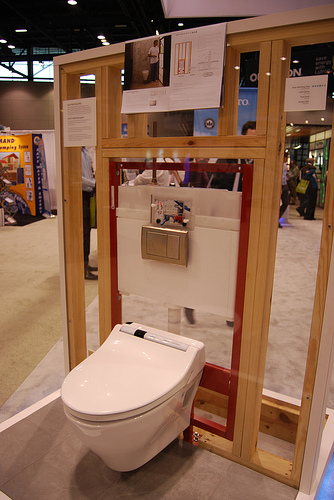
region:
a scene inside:
[4, 3, 333, 494]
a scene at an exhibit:
[1, 2, 325, 497]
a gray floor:
[2, 203, 333, 431]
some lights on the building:
[55, 0, 132, 51]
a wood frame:
[36, 0, 330, 498]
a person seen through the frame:
[77, 117, 110, 296]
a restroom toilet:
[58, 314, 214, 498]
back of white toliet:
[120, 319, 201, 363]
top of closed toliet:
[52, 320, 179, 436]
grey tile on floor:
[182, 472, 225, 492]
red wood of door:
[215, 369, 233, 386]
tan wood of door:
[244, 369, 255, 401]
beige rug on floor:
[19, 330, 51, 373]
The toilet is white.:
[53, 319, 211, 475]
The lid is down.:
[54, 312, 202, 421]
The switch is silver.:
[127, 223, 196, 268]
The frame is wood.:
[51, 62, 332, 409]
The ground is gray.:
[0, 398, 295, 498]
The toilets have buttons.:
[119, 319, 189, 358]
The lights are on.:
[93, 31, 112, 52]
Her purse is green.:
[295, 176, 309, 192]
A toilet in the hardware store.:
[71, 321, 197, 454]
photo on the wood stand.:
[121, 46, 230, 77]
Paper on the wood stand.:
[57, 95, 106, 145]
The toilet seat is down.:
[70, 335, 163, 404]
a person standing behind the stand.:
[69, 138, 103, 276]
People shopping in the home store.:
[279, 149, 314, 225]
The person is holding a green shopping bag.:
[298, 166, 311, 191]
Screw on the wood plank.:
[192, 419, 207, 442]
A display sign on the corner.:
[6, 133, 51, 219]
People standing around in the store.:
[280, 148, 318, 219]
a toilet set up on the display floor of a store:
[47, 168, 246, 482]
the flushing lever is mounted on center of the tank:
[138, 205, 194, 267]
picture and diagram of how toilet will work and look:
[119, 22, 239, 115]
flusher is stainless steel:
[136, 221, 188, 266]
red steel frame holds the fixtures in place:
[109, 156, 255, 444]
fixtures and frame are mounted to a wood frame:
[0, 3, 333, 497]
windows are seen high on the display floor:
[1, 60, 122, 84]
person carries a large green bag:
[297, 154, 319, 219]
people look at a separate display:
[278, 149, 332, 232]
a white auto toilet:
[51, 310, 213, 469]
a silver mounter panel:
[132, 221, 195, 271]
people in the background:
[276, 143, 320, 227]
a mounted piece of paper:
[278, 71, 331, 120]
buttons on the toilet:
[116, 319, 199, 355]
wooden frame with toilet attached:
[53, 38, 332, 491]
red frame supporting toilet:
[107, 160, 253, 451]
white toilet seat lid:
[59, 320, 206, 421]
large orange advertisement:
[0, 133, 43, 227]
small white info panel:
[60, 96, 96, 147]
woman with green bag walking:
[296, 157, 317, 221]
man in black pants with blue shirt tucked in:
[82, 145, 95, 280]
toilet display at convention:
[0, 9, 329, 496]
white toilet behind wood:
[47, 306, 223, 480]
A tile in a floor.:
[10, 416, 70, 458]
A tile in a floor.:
[5, 454, 90, 497]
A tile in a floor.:
[46, 430, 108, 480]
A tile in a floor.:
[150, 441, 212, 482]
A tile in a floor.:
[211, 456, 288, 498]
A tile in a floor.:
[107, 476, 146, 496]